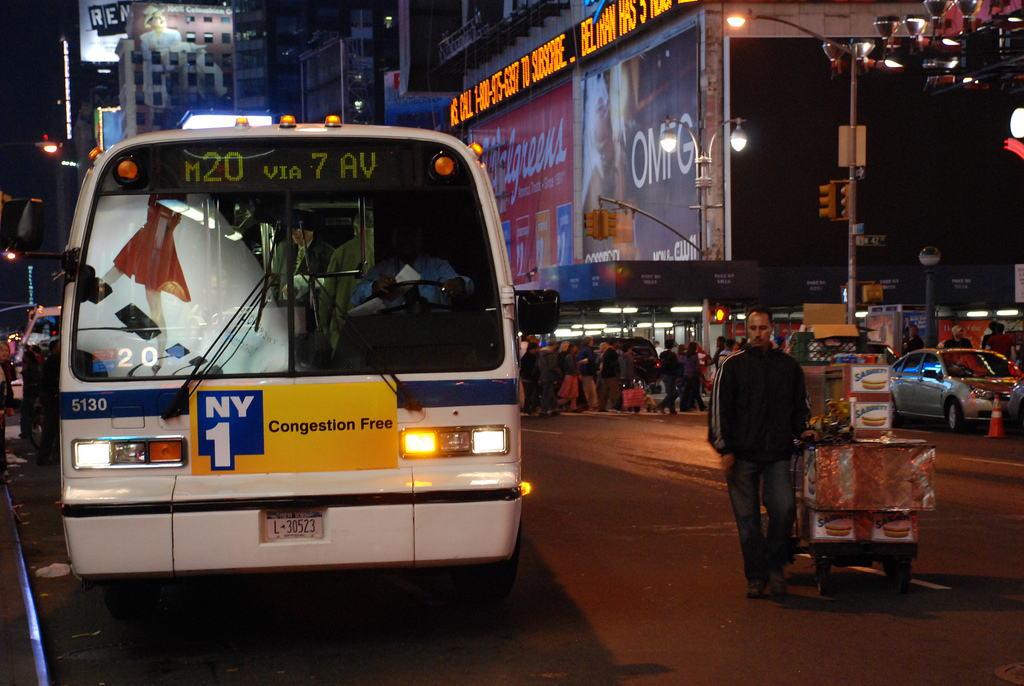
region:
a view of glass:
[69, 133, 513, 453]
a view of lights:
[382, 379, 586, 509]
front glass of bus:
[84, 145, 495, 485]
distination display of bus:
[154, 132, 421, 237]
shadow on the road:
[509, 613, 609, 665]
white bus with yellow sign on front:
[59, 116, 527, 598]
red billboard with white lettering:
[454, 86, 585, 295]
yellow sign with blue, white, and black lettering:
[181, 377, 396, 479]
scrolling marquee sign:
[438, 4, 699, 137]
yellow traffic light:
[813, 164, 865, 234]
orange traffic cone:
[972, 388, 1004, 443]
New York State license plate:
[251, 499, 335, 553]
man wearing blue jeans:
[710, 304, 809, 603]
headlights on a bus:
[67, 414, 510, 471]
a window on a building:
[150, 36, 164, 65]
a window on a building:
[150, 70, 157, 80]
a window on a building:
[154, 89, 171, 105]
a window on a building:
[169, 41, 177, 60]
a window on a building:
[166, 82, 179, 99]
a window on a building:
[173, 47, 178, 63]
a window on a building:
[185, 63, 193, 83]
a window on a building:
[185, 44, 204, 63]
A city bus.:
[56, 114, 531, 609]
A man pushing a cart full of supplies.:
[698, 288, 817, 598]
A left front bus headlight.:
[472, 421, 515, 456]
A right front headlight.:
[72, 434, 108, 470]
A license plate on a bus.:
[254, 499, 331, 544]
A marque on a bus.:
[151, 140, 412, 199]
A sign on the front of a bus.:
[188, 368, 400, 485]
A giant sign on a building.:
[466, 16, 707, 289]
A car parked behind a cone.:
[883, 344, 1020, 436]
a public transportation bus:
[46, 119, 537, 592]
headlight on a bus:
[69, 429, 193, 474]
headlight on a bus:
[392, 421, 517, 461]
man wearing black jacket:
[699, 304, 817, 609]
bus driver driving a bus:
[350, 217, 491, 325]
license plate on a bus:
[249, 502, 329, 551]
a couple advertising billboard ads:
[446, 23, 713, 274]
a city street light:
[721, 10, 880, 327]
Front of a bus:
[3, 107, 538, 623]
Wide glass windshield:
[66, 130, 512, 387]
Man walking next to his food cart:
[702, 300, 940, 607]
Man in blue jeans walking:
[704, 300, 815, 605]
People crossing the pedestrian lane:
[524, 326, 708, 421]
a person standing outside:
[661, 360, 680, 399]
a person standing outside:
[742, 293, 851, 551]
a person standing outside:
[541, 290, 643, 392]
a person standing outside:
[530, 376, 572, 416]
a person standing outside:
[570, 316, 610, 399]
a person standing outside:
[533, 304, 613, 410]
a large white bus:
[66, 126, 516, 575]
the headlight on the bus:
[403, 430, 508, 449]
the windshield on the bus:
[92, 187, 486, 353]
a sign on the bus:
[195, 386, 392, 466]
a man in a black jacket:
[714, 309, 797, 526]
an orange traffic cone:
[986, 399, 1007, 438]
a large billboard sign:
[455, 73, 721, 271]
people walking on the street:
[517, 335, 734, 406]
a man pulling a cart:
[698, 315, 927, 569]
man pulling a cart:
[691, 304, 821, 612]